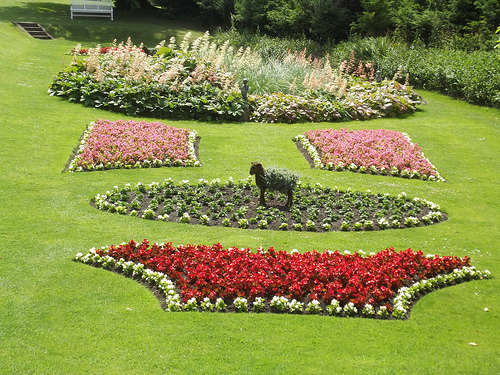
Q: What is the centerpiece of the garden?
A: An animal.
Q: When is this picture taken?
A: During the day.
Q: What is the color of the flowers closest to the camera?
A: Red.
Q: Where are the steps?
A: Upper left corner.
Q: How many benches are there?
A: One.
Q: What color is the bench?
A: White.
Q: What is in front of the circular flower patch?
A: A statue.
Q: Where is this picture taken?
A: In a grassy field.